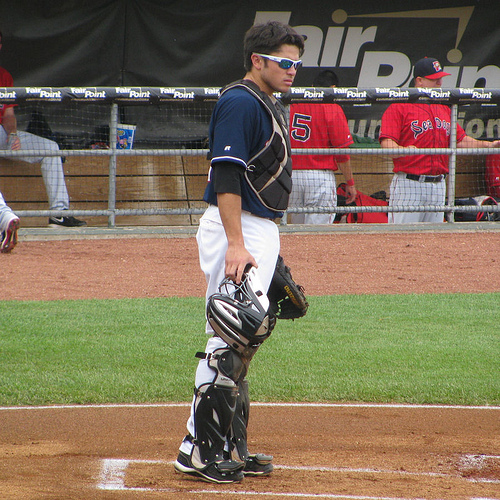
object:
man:
[174, 21, 307, 485]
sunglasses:
[250, 53, 305, 69]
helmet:
[207, 265, 277, 355]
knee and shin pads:
[194, 348, 240, 465]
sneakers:
[173, 435, 246, 484]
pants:
[186, 206, 280, 441]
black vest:
[203, 81, 293, 219]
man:
[378, 57, 500, 224]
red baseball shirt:
[379, 104, 467, 175]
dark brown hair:
[243, 20, 305, 71]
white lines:
[100, 456, 161, 493]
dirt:
[1, 404, 499, 494]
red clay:
[2, 230, 500, 299]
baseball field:
[0, 232, 499, 498]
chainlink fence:
[0, 86, 499, 229]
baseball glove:
[267, 255, 310, 321]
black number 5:
[291, 112, 311, 141]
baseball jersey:
[290, 103, 354, 170]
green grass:
[0, 293, 500, 408]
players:
[0, 56, 500, 250]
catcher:
[174, 18, 309, 484]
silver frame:
[279, 59, 293, 69]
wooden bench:
[0, 140, 500, 220]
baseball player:
[0, 63, 87, 228]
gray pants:
[0, 127, 79, 214]